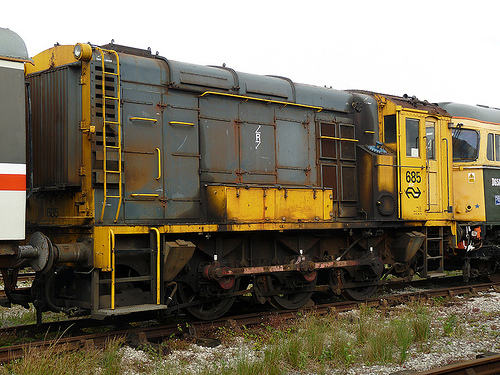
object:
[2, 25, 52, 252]
train car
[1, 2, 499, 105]
clouds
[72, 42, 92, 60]
light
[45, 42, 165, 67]
top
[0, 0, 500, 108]
sky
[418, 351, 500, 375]
tracks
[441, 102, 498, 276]
train car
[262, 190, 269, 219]
rust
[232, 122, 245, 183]
rust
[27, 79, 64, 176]
rust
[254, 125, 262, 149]
design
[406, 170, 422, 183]
685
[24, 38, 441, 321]
car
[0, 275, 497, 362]
tracks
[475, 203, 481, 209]
star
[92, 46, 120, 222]
ladder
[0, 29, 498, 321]
train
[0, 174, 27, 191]
stripe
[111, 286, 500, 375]
gravel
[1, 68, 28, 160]
grey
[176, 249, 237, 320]
wheel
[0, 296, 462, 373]
grass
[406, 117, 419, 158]
window